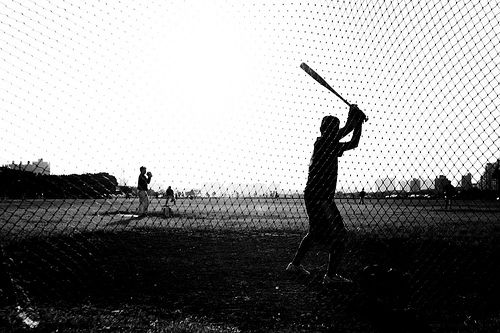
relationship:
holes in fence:
[1, 0, 496, 330] [2, 0, 497, 332]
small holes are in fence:
[146, 210, 204, 270] [21, 252, 123, 321]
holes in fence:
[210, 201, 230, 224] [2, 0, 497, 332]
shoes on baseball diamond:
[284, 258, 353, 287] [272, 64, 358, 291]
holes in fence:
[70, 121, 132, 206] [0, 0, 499, 236]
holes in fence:
[0, 1, 500, 236] [17, 13, 289, 265]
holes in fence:
[138, 197, 265, 231] [0, 0, 499, 236]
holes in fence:
[174, 146, 235, 208] [3, 5, 493, 219]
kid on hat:
[282, 103, 369, 289] [320, 115, 339, 127]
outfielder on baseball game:
[161, 184, 180, 210] [122, 49, 377, 256]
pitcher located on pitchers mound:
[133, 161, 153, 219] [93, 208, 198, 221]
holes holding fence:
[215, 223, 252, 250] [7, 9, 472, 323]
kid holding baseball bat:
[282, 104, 369, 293] [297, 58, 372, 122]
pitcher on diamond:
[133, 165, 154, 217] [117, 209, 140, 222]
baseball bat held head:
[297, 58, 367, 120] [311, 113, 345, 132]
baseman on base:
[440, 183, 461, 210] [131, 200, 169, 227]